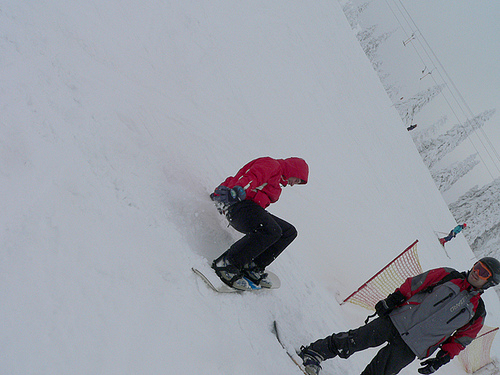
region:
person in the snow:
[187, 155, 317, 293]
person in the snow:
[268, 247, 498, 374]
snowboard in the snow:
[189, 262, 286, 298]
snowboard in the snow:
[268, 315, 303, 373]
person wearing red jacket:
[190, 155, 323, 302]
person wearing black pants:
[184, 156, 325, 302]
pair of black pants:
[214, 194, 302, 276]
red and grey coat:
[375, 266, 488, 358]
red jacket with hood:
[212, 154, 314, 208]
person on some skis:
[426, 216, 480, 258]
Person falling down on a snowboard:
[176, 141, 330, 313]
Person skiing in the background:
[424, 218, 486, 259]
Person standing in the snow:
[400, 121, 426, 136]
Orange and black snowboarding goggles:
[468, 252, 493, 282]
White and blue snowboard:
[187, 255, 292, 302]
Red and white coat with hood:
[215, 148, 333, 205]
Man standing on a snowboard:
[269, 239, 499, 374]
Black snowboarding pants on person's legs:
[181, 200, 311, 274]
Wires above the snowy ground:
[377, 5, 499, 194]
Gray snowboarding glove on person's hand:
[200, 185, 253, 212]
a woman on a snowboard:
[197, 155, 308, 290]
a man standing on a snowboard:
[297, 255, 497, 373]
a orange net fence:
[340, 239, 417, 309]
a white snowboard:
[186, 265, 280, 292]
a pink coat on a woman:
[206, 155, 309, 209]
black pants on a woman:
[222, 202, 296, 274]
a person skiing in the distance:
[432, 222, 465, 259]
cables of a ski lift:
[383, 1, 497, 178]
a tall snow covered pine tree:
[421, 113, 497, 161]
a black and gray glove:
[371, 290, 406, 312]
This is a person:
[202, 143, 317, 303]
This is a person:
[294, 248, 495, 373]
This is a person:
[434, 213, 471, 246]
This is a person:
[397, 114, 422, 141]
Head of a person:
[276, 148, 316, 198]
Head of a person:
[467, 249, 497, 293]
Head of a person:
[461, 218, 469, 231]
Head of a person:
[414, 122, 418, 129]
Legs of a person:
[209, 206, 304, 318]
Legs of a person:
[289, 312, 413, 374]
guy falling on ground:
[179, 138, 326, 303]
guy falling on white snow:
[186, 126, 326, 304]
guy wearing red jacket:
[178, 138, 323, 303]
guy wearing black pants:
[186, 137, 326, 304]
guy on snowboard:
[188, 134, 327, 303]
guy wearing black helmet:
[283, 227, 498, 374]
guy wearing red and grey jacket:
[293, 243, 495, 372]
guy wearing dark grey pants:
[271, 248, 498, 373]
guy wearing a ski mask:
[289, 249, 499, 374]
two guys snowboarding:
[185, 140, 499, 374]